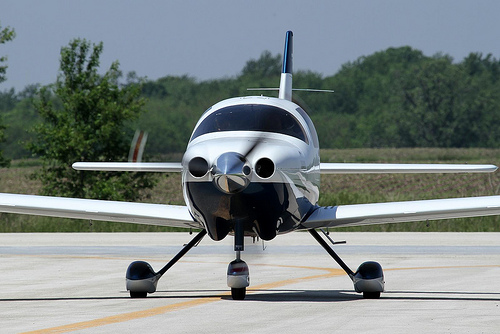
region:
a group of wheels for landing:
[277, 258, 279, 305]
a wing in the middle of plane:
[323, 152, 498, 167]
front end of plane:
[162, 126, 320, 239]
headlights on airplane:
[184, 148, 276, 196]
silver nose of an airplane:
[188, 148, 257, 192]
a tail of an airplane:
[246, 25, 342, 91]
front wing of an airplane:
[311, 185, 499, 225]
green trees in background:
[305, 57, 499, 125]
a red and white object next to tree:
[32, 32, 172, 187]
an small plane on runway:
[3, 2, 405, 327]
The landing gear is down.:
[120, 257, 410, 317]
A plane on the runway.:
[147, 92, 434, 247]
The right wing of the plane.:
[52, 131, 167, 191]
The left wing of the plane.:
[341, 133, 481, 186]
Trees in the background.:
[73, 42, 476, 131]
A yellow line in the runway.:
[71, 298, 223, 323]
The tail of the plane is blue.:
[270, 23, 311, 123]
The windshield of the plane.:
[206, 93, 306, 148]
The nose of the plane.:
[206, 149, 260, 214]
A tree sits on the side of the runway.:
[36, 58, 148, 209]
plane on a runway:
[1, 21, 496, 302]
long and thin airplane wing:
[320, 156, 497, 177]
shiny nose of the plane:
[213, 150, 248, 195]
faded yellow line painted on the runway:
[38, 266, 337, 333]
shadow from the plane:
[144, 277, 490, 307]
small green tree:
[28, 37, 172, 218]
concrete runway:
[1, 231, 498, 333]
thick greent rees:
[3, 48, 498, 147]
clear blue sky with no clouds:
[2, 2, 498, 93]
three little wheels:
[118, 256, 402, 308]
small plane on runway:
[50, 32, 437, 331]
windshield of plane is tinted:
[183, 94, 311, 149]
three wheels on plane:
[124, 241, 399, 301]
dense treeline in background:
[14, 29, 499, 139]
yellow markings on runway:
[115, 230, 436, 296]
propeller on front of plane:
[164, 114, 319, 219]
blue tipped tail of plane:
[259, 25, 309, 93]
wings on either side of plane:
[12, 180, 496, 234]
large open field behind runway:
[28, 136, 496, 196]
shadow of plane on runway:
[211, 265, 416, 299]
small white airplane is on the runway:
[0, 30, 499, 332]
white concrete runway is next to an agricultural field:
[0, 147, 499, 332]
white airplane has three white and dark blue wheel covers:
[0, 30, 499, 300]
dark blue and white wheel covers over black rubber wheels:
[123, 259, 388, 301]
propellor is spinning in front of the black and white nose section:
[181, 93, 320, 240]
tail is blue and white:
[243, 30, 335, 102]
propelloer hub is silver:
[209, 150, 254, 193]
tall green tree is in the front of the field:
[0, 35, 499, 232]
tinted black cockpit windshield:
[187, 102, 309, 146]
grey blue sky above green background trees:
[0, 0, 499, 150]